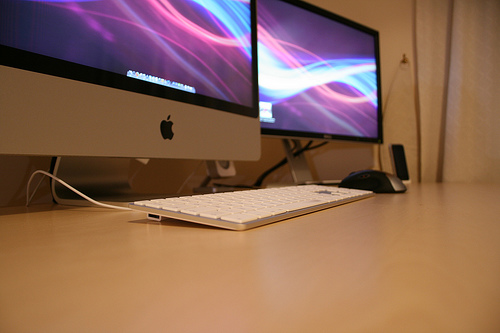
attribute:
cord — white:
[20, 162, 155, 223]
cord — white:
[167, 147, 227, 197]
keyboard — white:
[129, 179, 384, 249]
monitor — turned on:
[0, 0, 265, 162]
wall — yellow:
[384, 2, 499, 141]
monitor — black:
[255, 0, 380, 142]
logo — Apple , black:
[157, 112, 177, 142]